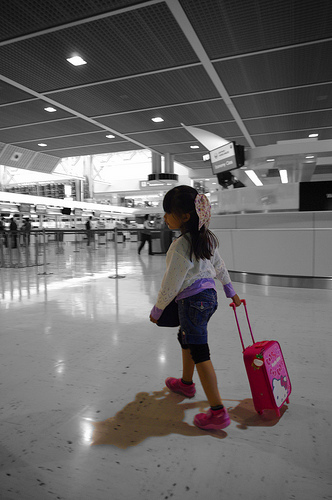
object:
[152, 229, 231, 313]
shirt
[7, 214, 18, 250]
person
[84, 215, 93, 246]
person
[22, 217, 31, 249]
person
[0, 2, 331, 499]
airport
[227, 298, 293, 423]
bag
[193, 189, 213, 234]
bow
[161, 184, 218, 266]
hair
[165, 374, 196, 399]
shoe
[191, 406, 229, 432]
shoe